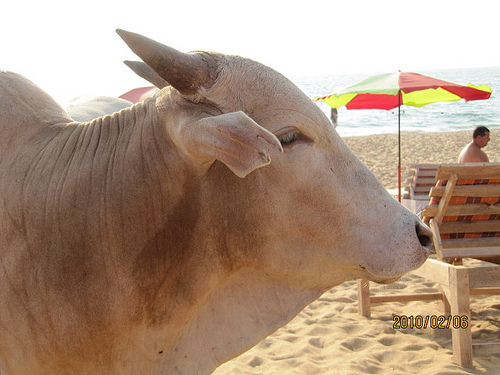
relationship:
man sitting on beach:
[457, 123, 494, 168] [211, 127, 499, 374]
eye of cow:
[276, 123, 312, 153] [3, 27, 435, 374]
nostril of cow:
[411, 218, 434, 251] [3, 27, 435, 374]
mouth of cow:
[358, 251, 427, 289] [3, 27, 435, 374]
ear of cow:
[180, 110, 285, 180] [3, 27, 435, 374]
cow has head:
[3, 27, 435, 374] [146, 54, 434, 302]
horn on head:
[115, 28, 216, 101] [146, 54, 434, 302]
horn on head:
[123, 58, 170, 93] [146, 54, 434, 302]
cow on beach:
[3, 27, 435, 374] [211, 127, 499, 374]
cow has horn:
[3, 27, 435, 374] [115, 28, 216, 101]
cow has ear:
[3, 27, 435, 374] [180, 110, 285, 180]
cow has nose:
[3, 27, 435, 374] [408, 216, 437, 263]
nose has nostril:
[408, 216, 437, 263] [411, 218, 434, 251]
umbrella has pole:
[311, 66, 493, 208] [396, 88, 405, 213]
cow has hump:
[3, 27, 435, 374] [1, 71, 75, 148]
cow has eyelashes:
[3, 27, 435, 374] [278, 130, 299, 143]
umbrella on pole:
[311, 66, 493, 208] [396, 88, 405, 213]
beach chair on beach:
[403, 160, 451, 203] [211, 127, 499, 374]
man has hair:
[457, 123, 494, 168] [472, 125, 488, 139]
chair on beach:
[360, 162, 499, 365] [211, 127, 499, 374]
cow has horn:
[3, 27, 435, 374] [123, 58, 170, 93]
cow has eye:
[3, 27, 435, 374] [276, 123, 312, 153]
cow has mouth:
[3, 27, 435, 374] [358, 251, 427, 289]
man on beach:
[457, 123, 494, 168] [211, 127, 499, 374]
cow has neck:
[3, 27, 435, 374] [110, 218, 330, 369]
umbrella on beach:
[311, 66, 493, 208] [211, 127, 499, 374]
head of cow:
[146, 54, 434, 302] [3, 27, 435, 374]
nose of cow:
[408, 216, 437, 263] [3, 27, 435, 374]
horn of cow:
[115, 28, 216, 101] [3, 27, 435, 374]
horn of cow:
[123, 58, 170, 93] [3, 27, 435, 374]